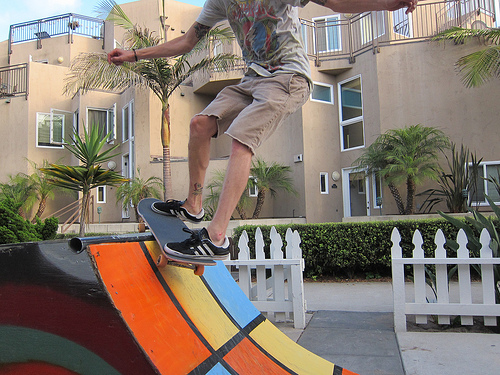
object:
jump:
[2, 232, 358, 375]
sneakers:
[163, 228, 231, 261]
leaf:
[387, 128, 408, 149]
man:
[105, 0, 418, 262]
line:
[189, 312, 266, 373]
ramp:
[5, 232, 361, 375]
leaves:
[235, 220, 499, 271]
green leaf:
[454, 40, 498, 89]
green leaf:
[417, 157, 439, 179]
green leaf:
[188, 51, 245, 79]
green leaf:
[87, 117, 102, 147]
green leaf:
[40, 173, 81, 191]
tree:
[428, 10, 500, 91]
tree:
[242, 156, 299, 218]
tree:
[60, 0, 246, 209]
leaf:
[370, 107, 460, 199]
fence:
[219, 225, 498, 329]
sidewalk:
[267, 312, 498, 372]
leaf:
[81, 157, 95, 188]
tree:
[44, 114, 126, 223]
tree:
[1, 205, 59, 245]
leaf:
[7, 220, 12, 224]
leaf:
[409, 136, 416, 146]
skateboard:
[137, 195, 217, 274]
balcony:
[207, 0, 500, 72]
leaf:
[411, 185, 452, 197]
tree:
[413, 137, 494, 216]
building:
[0, 0, 500, 238]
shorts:
[193, 73, 313, 151]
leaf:
[98, 138, 127, 161]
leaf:
[126, 18, 149, 44]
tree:
[350, 122, 454, 216]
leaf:
[88, 122, 100, 148]